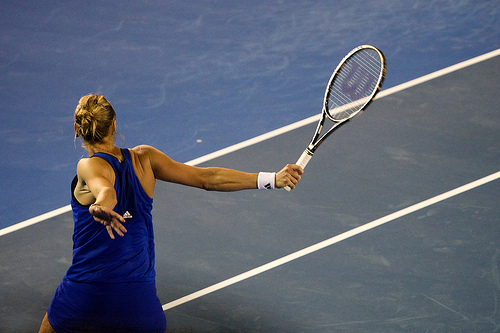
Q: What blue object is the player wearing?
A: Top.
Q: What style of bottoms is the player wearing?
A: Shorts.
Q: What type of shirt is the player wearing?
A: Tank top.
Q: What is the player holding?
A: Tennis racket.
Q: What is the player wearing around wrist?
A: Band.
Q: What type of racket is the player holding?
A: Tennis.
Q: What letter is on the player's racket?
A: W.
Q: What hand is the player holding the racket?
A: Right.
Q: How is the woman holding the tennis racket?
A: In the right hand.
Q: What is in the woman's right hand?
A: White handle of a tennis racket.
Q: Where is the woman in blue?
A: Tennis court.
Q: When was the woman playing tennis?
A: Tennis match.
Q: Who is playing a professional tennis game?
A: A woman in blue.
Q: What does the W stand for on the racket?
A: Wilson's.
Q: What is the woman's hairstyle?
A: Bun.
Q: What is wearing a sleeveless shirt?
A: The player.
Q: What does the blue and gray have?
A: White lines.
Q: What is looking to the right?
A: The player.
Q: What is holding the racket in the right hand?
A: The player.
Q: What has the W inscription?
A: The racket.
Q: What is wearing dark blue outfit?
A: The player.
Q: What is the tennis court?
A: Blue.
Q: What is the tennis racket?
A: Black and white.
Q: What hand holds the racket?
A: Right.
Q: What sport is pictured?
A: Tennis.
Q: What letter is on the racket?
A: W.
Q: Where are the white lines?
A: On the ground.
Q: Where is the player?
A: Left.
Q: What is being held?
A: Tennis racket.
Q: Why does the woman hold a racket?
A: To play tennis.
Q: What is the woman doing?
A: Swinging a racket.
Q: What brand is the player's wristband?
A: Adidas.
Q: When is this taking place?
A: Daytime.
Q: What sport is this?
A: Tennis.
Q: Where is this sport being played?
A: Tennis court.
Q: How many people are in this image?
A: One.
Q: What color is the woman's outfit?
A: Blue.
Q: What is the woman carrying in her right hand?
A: Tennis racket.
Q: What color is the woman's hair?
A: Blonde.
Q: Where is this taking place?
A: On a tennis court.